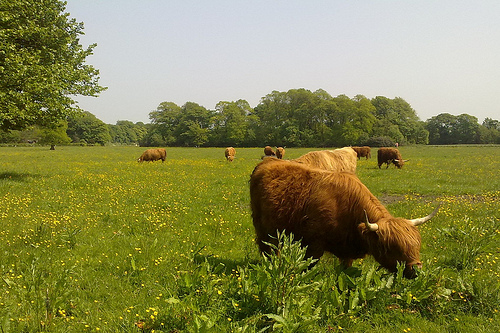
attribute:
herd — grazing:
[138, 144, 438, 282]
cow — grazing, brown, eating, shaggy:
[249, 154, 433, 280]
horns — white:
[359, 200, 443, 233]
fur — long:
[248, 159, 438, 248]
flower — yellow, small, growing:
[55, 305, 79, 323]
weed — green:
[126, 259, 146, 282]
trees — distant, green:
[1, 2, 497, 150]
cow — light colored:
[292, 148, 362, 173]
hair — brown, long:
[375, 220, 431, 253]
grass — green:
[3, 143, 499, 332]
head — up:
[276, 147, 286, 158]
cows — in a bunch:
[138, 144, 444, 282]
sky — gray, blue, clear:
[43, 1, 499, 124]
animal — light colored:
[289, 147, 361, 177]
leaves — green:
[1, 0, 108, 131]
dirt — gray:
[374, 184, 443, 202]